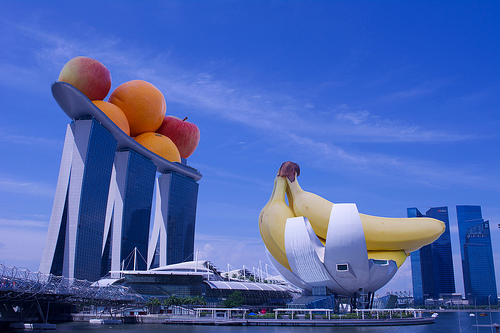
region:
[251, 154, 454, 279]
huge bananas bunch on top of building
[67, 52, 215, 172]
fruits on top of buldings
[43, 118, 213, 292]
three tall skyscraper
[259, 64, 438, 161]
blue sky with soft coulds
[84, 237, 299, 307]
white roof tops on large building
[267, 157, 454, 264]
large bright yellow bananas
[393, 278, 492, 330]
City near clear water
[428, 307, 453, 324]
two white boats on the water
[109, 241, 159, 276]
white poles coming down a pole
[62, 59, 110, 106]
mango on top of a steal structure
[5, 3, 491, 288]
the sky is blue.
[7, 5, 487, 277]
clouds in the sky.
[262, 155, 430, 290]
bananas in a bunch.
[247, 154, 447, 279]
the banana is yellow.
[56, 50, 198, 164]
apples and oranges on a building.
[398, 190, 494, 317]
building in the background.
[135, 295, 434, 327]
boat in the water.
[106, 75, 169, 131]
the fruit is orange.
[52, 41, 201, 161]
fruit stacked in a pile.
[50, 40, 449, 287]
the fruit is big.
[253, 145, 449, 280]
the bananas on top of the building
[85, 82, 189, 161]
the oranges on top of the building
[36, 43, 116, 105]
the peach on top of the building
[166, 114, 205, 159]
the apple on top of the building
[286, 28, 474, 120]
the sky is blue and peaceful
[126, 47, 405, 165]
a cloud in the sky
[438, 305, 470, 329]
the water is calm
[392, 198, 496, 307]
the buildings are tall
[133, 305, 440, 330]
the marina next to the buildings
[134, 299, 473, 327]
the marina is empty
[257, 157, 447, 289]
Banana in a building bowl.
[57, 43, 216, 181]
Oranges on the board.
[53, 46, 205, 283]
Three bulidings and a board on top.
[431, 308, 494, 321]
boats on the water.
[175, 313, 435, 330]
A dock on the water.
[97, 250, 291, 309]
A cruise ship.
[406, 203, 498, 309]
High rise building.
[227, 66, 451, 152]
clouds in the sky.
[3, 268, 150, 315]
A bridge oer the water.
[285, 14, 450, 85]
The sky is blue.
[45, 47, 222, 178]
huge oranges and apples on top of building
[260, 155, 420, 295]
huge bananas on top of building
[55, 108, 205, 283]
3 shiny buildings under the oranges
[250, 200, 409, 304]
white tulip-shaped building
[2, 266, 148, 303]
coil-like bridge over the wwater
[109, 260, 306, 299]
shorter building with white roofs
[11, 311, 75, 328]
boat going under the bridge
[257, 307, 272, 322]
small red structure between the rectangular arches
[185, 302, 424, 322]
row of white rectangular arches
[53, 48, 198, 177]
3 oranges and 2 apples